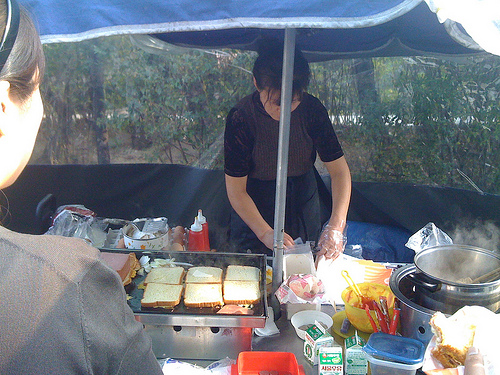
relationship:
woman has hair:
[224, 37, 353, 260] [251, 42, 313, 107]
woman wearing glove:
[224, 37, 353, 260] [314, 214, 349, 262]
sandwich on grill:
[140, 281, 184, 309] [98, 247, 268, 362]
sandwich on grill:
[143, 266, 186, 285] [98, 247, 268, 362]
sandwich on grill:
[184, 282, 223, 308] [98, 247, 268, 362]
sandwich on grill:
[223, 281, 261, 303] [98, 247, 268, 362]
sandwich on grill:
[184, 266, 222, 283] [98, 247, 268, 362]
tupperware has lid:
[362, 331, 425, 374] [363, 332, 426, 363]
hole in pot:
[418, 325, 426, 335] [388, 243, 498, 346]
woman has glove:
[224, 37, 353, 260] [314, 214, 349, 262]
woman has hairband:
[0, 0, 165, 374] [0, 0, 21, 69]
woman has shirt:
[0, 0, 165, 374] [0, 225, 165, 375]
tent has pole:
[16, 0, 500, 61] [269, 27, 298, 320]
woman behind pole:
[224, 37, 353, 260] [269, 27, 298, 320]